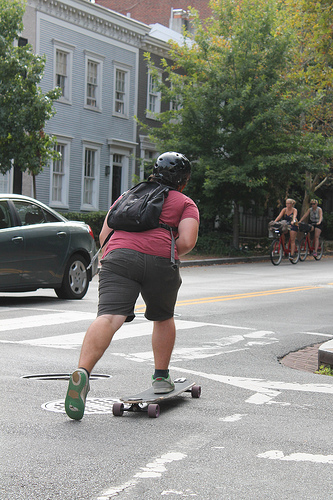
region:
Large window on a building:
[47, 49, 68, 96]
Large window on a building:
[80, 56, 101, 117]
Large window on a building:
[109, 62, 129, 122]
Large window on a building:
[142, 65, 161, 118]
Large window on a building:
[45, 129, 68, 203]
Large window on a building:
[76, 141, 109, 213]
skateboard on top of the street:
[112, 377, 200, 417]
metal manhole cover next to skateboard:
[42, 396, 131, 414]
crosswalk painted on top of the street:
[0, 305, 329, 401]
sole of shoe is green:
[63, 369, 84, 417]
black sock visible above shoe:
[152, 368, 168, 378]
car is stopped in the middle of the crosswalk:
[0, 193, 100, 298]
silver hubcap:
[67, 260, 88, 293]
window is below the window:
[47, 131, 68, 204]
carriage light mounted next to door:
[104, 164, 110, 175]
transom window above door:
[112, 154, 121, 163]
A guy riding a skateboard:
[60, 145, 204, 422]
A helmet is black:
[146, 144, 191, 191]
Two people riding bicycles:
[261, 189, 323, 264]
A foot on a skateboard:
[108, 369, 200, 417]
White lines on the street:
[0, 299, 328, 493]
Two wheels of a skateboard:
[106, 395, 159, 417]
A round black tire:
[50, 249, 91, 301]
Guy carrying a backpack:
[88, 141, 199, 267]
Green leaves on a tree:
[0, 0, 60, 175]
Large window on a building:
[45, 44, 76, 99]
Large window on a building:
[79, 51, 108, 115]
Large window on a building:
[107, 60, 133, 123]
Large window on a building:
[143, 60, 162, 121]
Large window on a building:
[46, 135, 71, 210]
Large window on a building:
[75, 135, 99, 214]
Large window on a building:
[161, 70, 192, 119]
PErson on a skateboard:
[57, 151, 209, 442]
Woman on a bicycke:
[266, 185, 301, 271]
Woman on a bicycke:
[297, 195, 320, 258]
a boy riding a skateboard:
[62, 150, 199, 423]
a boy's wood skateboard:
[109, 376, 200, 419]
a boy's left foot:
[64, 369, 89, 419]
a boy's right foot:
[148, 375, 176, 394]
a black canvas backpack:
[109, 181, 169, 232]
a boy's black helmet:
[155, 150, 193, 188]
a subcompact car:
[0, 192, 97, 298]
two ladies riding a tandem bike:
[265, 197, 324, 262]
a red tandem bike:
[266, 220, 324, 262]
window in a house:
[51, 39, 70, 106]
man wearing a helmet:
[51, 147, 213, 421]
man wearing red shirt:
[62, 141, 193, 389]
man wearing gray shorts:
[56, 145, 203, 391]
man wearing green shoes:
[44, 150, 211, 425]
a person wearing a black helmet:
[129, 145, 199, 207]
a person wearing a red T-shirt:
[97, 146, 202, 274]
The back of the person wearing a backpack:
[92, 145, 201, 272]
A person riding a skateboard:
[62, 148, 225, 423]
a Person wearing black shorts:
[83, 147, 201, 338]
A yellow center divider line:
[210, 289, 312, 298]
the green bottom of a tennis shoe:
[61, 365, 90, 425]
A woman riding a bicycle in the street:
[267, 195, 305, 273]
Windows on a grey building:
[79, 41, 108, 120]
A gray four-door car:
[6, 192, 99, 301]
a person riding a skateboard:
[64, 151, 201, 419]